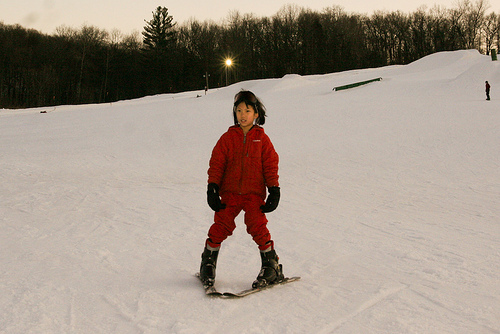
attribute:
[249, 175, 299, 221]
glove — black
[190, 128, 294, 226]
jacket — red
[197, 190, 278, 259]
pants — red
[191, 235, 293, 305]
shoes — black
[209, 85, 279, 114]
hair — black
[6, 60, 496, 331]
snow — white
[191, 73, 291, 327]
child — dressed for snow